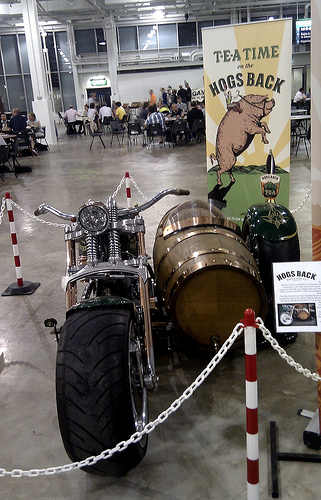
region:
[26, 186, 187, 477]
motorcycle with a thick tire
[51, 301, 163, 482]
fat grooved tire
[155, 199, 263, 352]
big brown barrel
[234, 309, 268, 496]
thin white and red pole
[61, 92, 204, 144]
group of people sitting in chairs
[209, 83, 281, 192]
image of a man riding a giant hog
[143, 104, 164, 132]
man wearing a checkered shirt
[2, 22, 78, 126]
tall glass windows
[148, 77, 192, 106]
line of people standing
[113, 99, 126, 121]
someone wearing a yellow shirt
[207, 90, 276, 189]
drawing of man riding large hog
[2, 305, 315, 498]
two white chain links on pole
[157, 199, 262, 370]
large wooden barrel with metal detail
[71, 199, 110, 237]
round shiny motorcycle headlight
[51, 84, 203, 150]
several people seated at tables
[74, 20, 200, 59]
several shiny rectangular windows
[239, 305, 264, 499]
red and white striped metal pole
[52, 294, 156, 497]
wide black front motorcycle tire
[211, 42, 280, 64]
green lettered tea time sign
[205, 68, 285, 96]
black lettered hogs back sign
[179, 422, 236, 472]
a shinny grey floor.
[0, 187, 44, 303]
a red and white pole.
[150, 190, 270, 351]
a big brown barrel.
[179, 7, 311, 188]
a big yellow and white sign with a pig.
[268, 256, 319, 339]
a white sign says hogs back.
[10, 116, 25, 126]
a man is wearing a blue shirt.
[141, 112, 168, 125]
a man is wearing a plated blue and white shirt.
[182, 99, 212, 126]
a man is wearing a black shirt.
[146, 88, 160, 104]
a man is wearing a orange shirt.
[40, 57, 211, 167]
a bunch of people are sitting at the table.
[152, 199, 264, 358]
Motorcycle sidecar shaped like a barrel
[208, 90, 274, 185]
Illustration of man riding giant hog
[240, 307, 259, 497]
Red and white exhibit boundary pole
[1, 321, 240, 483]
Plastic chain protecting exhibit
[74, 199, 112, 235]
Headlight on motorcycle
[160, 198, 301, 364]
Sidecar of motorcycle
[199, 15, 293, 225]
Beverage advertisement near motorcycle display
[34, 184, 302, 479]
Motorcycle with sidecar on display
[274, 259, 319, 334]
Information about displayed motorcycle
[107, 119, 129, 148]
Black plastic chair in exhibit hall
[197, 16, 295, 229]
Large banner with hog on it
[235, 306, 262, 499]
White and red pole with chains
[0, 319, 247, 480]
White chain link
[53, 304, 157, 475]
Large motorcycle wheel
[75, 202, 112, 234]
Chromed motorcyle front headlight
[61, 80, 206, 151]
Large group of people seated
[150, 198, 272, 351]
Barrel motorcyle seat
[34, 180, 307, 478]
Old classic motorcycle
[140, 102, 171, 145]
Man with white and blue striped shirt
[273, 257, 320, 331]
Hodsback motorcycle flyer with photo